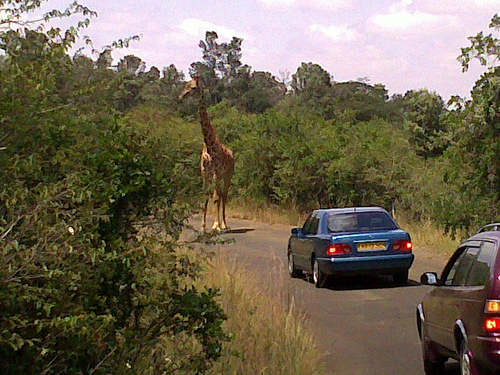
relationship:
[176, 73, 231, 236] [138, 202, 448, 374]
giraffe on road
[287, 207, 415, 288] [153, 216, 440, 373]
car on road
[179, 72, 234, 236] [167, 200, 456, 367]
giraffe on road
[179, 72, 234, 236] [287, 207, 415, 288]
giraffe in front of car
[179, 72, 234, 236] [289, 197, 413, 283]
giraffe in front of car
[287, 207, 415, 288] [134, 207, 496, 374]
car on road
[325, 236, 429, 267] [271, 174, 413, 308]
lights are on car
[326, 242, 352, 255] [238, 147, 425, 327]
lights are on car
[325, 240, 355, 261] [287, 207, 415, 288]
brake light are on car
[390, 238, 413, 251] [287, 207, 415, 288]
brake light are on car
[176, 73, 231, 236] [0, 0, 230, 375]
giraffe standing next to trees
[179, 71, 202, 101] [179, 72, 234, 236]
head of giraffe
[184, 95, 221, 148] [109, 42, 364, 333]
neck of giraffe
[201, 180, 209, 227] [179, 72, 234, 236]
giraffe leg of giraffe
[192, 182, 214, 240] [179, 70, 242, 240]
giraffe leg on giraffe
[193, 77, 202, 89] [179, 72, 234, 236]
ear of giraffe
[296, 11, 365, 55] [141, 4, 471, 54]
white clouds in purple sky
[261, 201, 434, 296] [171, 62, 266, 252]
car moving towards giraffe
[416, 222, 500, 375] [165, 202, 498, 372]
car on path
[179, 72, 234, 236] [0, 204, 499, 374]
giraffe walking on land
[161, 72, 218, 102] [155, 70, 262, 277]
head of giraffe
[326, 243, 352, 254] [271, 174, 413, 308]
brake light on car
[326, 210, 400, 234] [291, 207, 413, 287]
window on car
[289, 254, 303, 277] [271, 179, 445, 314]
tire on a car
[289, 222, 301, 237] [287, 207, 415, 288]
mirror on car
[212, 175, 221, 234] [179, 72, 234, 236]
leg of giraffe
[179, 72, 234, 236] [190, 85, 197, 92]
giraffe has eye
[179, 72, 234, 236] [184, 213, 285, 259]
giraffe on asphalt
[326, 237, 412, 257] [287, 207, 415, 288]
tail lights on back of car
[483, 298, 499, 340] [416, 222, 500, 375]
tail light of car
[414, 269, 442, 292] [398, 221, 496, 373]
mirror on car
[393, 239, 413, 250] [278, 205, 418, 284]
light on car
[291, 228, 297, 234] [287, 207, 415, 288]
mirror on car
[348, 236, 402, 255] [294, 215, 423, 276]
plate on back of car